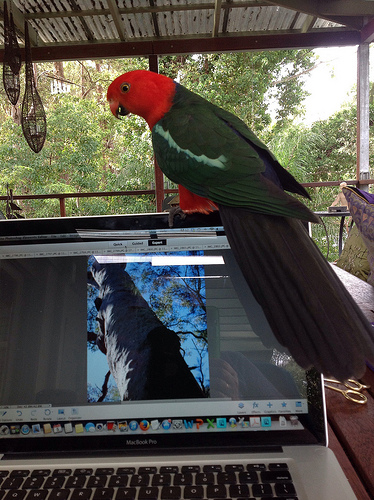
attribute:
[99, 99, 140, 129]
beak — red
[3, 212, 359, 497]
laptop —  white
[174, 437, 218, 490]
buttons —  black